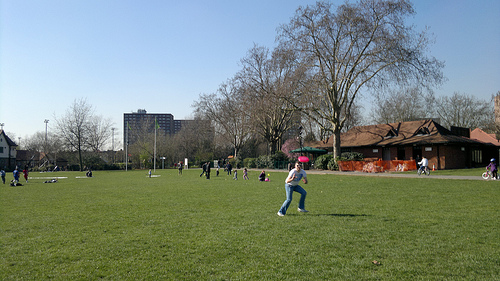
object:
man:
[275, 161, 310, 216]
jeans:
[278, 184, 309, 215]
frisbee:
[297, 155, 310, 163]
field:
[0, 168, 499, 281]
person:
[417, 155, 430, 174]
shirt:
[419, 158, 428, 166]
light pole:
[43, 123, 49, 148]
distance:
[1, 96, 233, 171]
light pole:
[110, 129, 116, 164]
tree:
[234, 0, 451, 167]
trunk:
[332, 117, 341, 163]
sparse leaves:
[393, 17, 404, 24]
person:
[85, 169, 93, 178]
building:
[123, 113, 175, 162]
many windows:
[124, 114, 208, 148]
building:
[306, 119, 494, 171]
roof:
[308, 119, 483, 149]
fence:
[338, 156, 418, 175]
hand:
[291, 173, 297, 181]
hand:
[301, 178, 308, 183]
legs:
[276, 185, 294, 217]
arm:
[285, 170, 295, 183]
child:
[484, 157, 498, 181]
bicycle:
[480, 167, 500, 180]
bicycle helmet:
[489, 158, 497, 163]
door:
[412, 147, 423, 169]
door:
[397, 148, 406, 161]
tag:
[395, 164, 405, 172]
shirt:
[284, 168, 308, 186]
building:
[0, 128, 18, 172]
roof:
[1, 130, 20, 147]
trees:
[188, 91, 263, 159]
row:
[226, 153, 343, 171]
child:
[242, 167, 251, 181]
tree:
[281, 136, 305, 160]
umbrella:
[287, 146, 327, 154]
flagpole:
[125, 120, 129, 172]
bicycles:
[416, 161, 432, 176]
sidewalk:
[189, 167, 499, 181]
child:
[147, 168, 153, 178]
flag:
[126, 120, 132, 131]